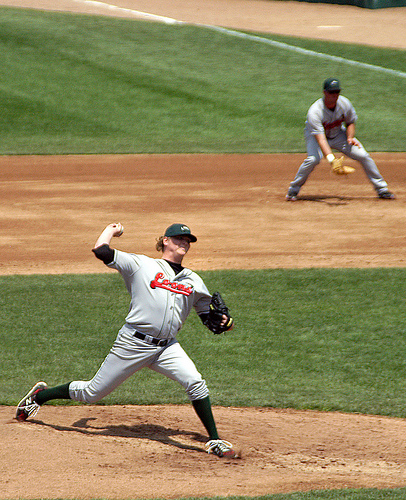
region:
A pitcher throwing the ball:
[12, 216, 245, 464]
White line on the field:
[85, 0, 404, 82]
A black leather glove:
[200, 286, 235, 339]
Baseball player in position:
[277, 69, 398, 207]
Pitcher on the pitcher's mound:
[1, 220, 403, 490]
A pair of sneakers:
[13, 377, 244, 464]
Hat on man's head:
[158, 217, 198, 262]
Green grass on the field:
[1, 2, 402, 498]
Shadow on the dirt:
[28, 408, 214, 459]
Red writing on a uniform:
[148, 266, 194, 301]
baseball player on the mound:
[18, 198, 260, 473]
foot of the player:
[202, 436, 237, 462]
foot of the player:
[10, 377, 58, 434]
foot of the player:
[281, 186, 301, 208]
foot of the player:
[370, 185, 401, 205]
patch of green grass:
[277, 372, 291, 389]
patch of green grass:
[365, 367, 384, 385]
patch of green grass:
[267, 342, 284, 359]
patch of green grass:
[66, 331, 79, 347]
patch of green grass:
[26, 326, 42, 343]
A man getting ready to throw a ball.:
[14, 218, 243, 461]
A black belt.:
[131, 328, 169, 347]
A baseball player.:
[15, 219, 252, 456]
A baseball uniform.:
[38, 248, 222, 442]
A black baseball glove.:
[209, 285, 233, 338]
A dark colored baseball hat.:
[164, 220, 199, 243]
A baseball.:
[114, 221, 125, 237]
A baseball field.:
[1, 1, 405, 499]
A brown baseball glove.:
[329, 156, 357, 175]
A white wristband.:
[324, 152, 339, 163]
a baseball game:
[62, 68, 379, 388]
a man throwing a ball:
[97, 219, 230, 336]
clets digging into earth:
[198, 417, 243, 464]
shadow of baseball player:
[51, 404, 193, 451]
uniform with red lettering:
[148, 269, 200, 300]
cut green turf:
[241, 280, 370, 377]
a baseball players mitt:
[324, 151, 361, 177]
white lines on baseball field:
[171, 14, 299, 53]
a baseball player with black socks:
[184, 382, 229, 435]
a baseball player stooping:
[287, 79, 394, 207]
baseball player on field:
[37, 195, 239, 444]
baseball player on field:
[280, 80, 378, 191]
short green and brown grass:
[19, 282, 66, 310]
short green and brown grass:
[267, 286, 302, 332]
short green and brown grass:
[256, 336, 324, 380]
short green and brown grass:
[325, 291, 366, 319]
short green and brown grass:
[29, 64, 92, 123]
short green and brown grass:
[120, 98, 171, 140]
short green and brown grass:
[181, 34, 236, 100]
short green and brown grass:
[56, 42, 126, 94]